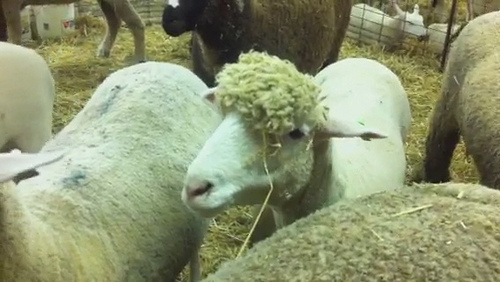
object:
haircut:
[212, 49, 329, 137]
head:
[180, 49, 391, 216]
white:
[348, 91, 399, 126]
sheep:
[180, 58, 412, 230]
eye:
[289, 128, 304, 140]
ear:
[315, 117, 388, 141]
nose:
[188, 181, 211, 196]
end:
[340, 57, 373, 63]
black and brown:
[180, 0, 327, 60]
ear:
[202, 87, 218, 113]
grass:
[364, 40, 435, 60]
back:
[423, 112, 460, 183]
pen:
[65, 5, 396, 147]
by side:
[109, 26, 341, 155]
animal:
[162, 0, 353, 88]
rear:
[311, 8, 393, 57]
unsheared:
[180, 5, 318, 35]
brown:
[259, 16, 326, 46]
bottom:
[91, 0, 144, 61]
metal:
[417, 34, 426, 41]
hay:
[50, 33, 107, 76]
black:
[181, 11, 236, 35]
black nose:
[162, 12, 179, 30]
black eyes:
[186, 2, 198, 10]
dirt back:
[99, 60, 155, 108]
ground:
[0, 0, 498, 279]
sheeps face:
[180, 110, 310, 217]